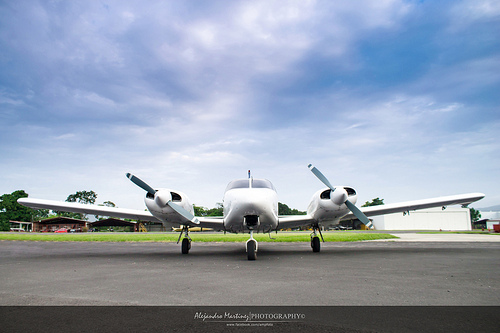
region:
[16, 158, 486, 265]
A white airplane thats parked on black asphalt.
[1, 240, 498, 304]
A large section of black asphalt.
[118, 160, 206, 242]
A white striped airplane blade.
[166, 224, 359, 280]
Three landing gears for an airplane.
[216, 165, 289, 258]
The cockpit of a white airplane.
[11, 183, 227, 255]
The right wing of a white airplane.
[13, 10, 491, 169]
Large poofy louds in a bright blue sky.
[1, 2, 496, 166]
A daylit sky.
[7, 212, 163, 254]
Brown and red airplane hangars in a field.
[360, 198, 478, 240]
a large white airplane hangar.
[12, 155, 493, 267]
a plane on a landing strip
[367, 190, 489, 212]
right wing of plane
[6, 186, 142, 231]
left wing of plane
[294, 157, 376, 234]
engine on right wing of plane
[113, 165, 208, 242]
engine on left wing of plane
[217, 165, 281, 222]
the cockpit of plane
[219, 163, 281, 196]
windows of the cockpit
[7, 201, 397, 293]
a field of grass behind a plane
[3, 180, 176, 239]
buildings behind a plane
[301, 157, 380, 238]
two blades of a propeller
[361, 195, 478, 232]
White airport hanger building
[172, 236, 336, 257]
Rubber tires of airplane landing gear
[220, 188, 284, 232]
White painted nose of airplane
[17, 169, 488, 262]
Airplane parked on runway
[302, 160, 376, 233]
Airplane propeller driven engine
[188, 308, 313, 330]
Photography business identification label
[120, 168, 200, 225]
Still propeller on airpalne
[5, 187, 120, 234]
Leaf covered trees in background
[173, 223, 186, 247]
Landing gear enclosure hatch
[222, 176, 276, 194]
Cockpit windshields on airplane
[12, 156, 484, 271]
plane at an airport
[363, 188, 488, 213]
wing on a plane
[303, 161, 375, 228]
propellers on a plane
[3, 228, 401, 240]
small stsrip of grass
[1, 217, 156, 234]
buildings behind the grass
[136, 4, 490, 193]
white fluffy clouds in the blue sky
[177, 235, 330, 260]
tires on the airplane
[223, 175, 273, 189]
windshield on the front of the plane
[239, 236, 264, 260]
front tire on the plane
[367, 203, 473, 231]
long white building in the background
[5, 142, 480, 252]
white airplane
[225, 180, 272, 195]
front windows of white airplane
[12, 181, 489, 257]
wings of the white airplane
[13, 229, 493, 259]
shadow of plane on cement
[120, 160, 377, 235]
two propellors on airplane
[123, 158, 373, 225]
propellors with two blades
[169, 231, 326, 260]
black wheels of the airplane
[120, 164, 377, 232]
propellor blades with white strips on their ends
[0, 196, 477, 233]
buildings behind white airplane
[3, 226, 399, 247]
patch of grass behind airplane